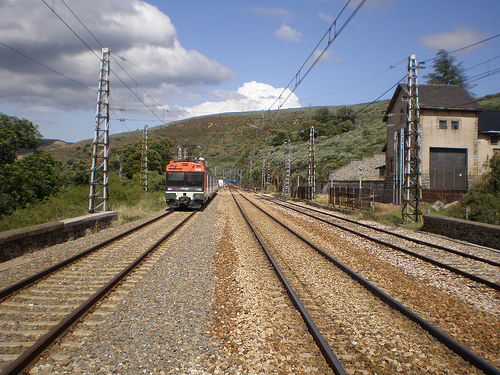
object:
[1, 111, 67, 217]
tree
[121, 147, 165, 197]
tree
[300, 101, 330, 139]
tree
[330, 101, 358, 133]
tree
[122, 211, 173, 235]
tracks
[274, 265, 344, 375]
train tracks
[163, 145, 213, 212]
train engine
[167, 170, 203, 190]
windshield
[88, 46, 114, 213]
tower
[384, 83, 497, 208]
building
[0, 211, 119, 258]
wall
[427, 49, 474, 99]
tree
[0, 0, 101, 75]
wire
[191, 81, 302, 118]
cloud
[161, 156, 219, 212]
train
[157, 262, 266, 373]
gravel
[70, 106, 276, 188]
hills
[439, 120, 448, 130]
windows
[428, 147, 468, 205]
door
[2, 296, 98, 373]
tracks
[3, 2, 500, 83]
sky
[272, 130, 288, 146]
trees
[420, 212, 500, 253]
curb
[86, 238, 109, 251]
metal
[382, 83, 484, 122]
roof